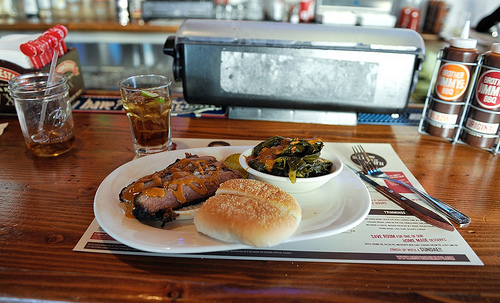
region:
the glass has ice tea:
[136, 78, 176, 148]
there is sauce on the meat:
[130, 153, 209, 220]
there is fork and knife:
[353, 146, 460, 239]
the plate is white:
[96, 168, 123, 250]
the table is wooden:
[0, 162, 69, 300]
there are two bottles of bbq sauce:
[428, 63, 498, 143]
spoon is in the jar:
[19, 69, 56, 163]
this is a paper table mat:
[356, 212, 448, 262]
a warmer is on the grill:
[172, 23, 407, 114]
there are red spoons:
[9, 31, 74, 67]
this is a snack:
[203, 183, 288, 240]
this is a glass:
[118, 75, 178, 142]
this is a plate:
[304, 188, 366, 230]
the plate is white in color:
[311, 197, 329, 215]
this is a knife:
[374, 189, 399, 199]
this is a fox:
[358, 146, 380, 169]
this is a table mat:
[369, 232, 467, 261]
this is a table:
[10, 175, 62, 281]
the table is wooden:
[16, 190, 51, 255]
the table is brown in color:
[20, 167, 48, 234]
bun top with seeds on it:
[193, 170, 308, 250]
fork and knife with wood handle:
[350, 143, 477, 242]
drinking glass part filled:
[118, 66, 175, 158]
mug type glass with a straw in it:
[9, 47, 78, 162]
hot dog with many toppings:
[120, 149, 224, 228]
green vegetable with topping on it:
[232, 131, 347, 193]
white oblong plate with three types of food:
[88, 128, 375, 256]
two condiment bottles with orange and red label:
[422, 41, 498, 156]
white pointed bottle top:
[441, 16, 483, 61]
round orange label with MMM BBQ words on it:
[430, 57, 477, 106]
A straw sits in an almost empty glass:
[17, 66, 84, 164]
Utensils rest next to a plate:
[343, 141, 481, 235]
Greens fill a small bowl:
[245, 125, 342, 191]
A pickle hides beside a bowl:
[218, 148, 253, 184]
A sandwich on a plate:
[116, 147, 276, 244]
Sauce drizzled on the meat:
[140, 152, 224, 212]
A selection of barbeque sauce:
[407, 100, 497, 144]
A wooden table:
[13, 174, 85, 272]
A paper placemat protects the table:
[342, 136, 493, 274]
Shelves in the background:
[99, 0, 172, 52]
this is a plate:
[320, 197, 360, 225]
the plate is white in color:
[322, 219, 342, 231]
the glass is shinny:
[31, 92, 73, 120]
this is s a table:
[13, 209, 43, 275]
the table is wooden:
[5, 180, 59, 265]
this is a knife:
[377, 182, 399, 207]